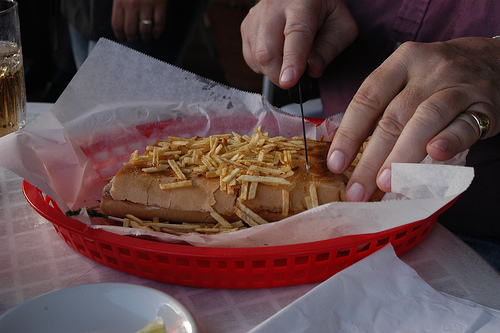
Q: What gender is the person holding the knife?
A: Male.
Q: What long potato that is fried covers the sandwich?
A: French fries.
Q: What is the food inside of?
A: A food basket.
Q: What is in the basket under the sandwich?
A: White paper.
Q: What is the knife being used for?
A: Cutting the sandwich.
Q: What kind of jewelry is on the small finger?
A: A ring.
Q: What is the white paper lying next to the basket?
A: A napkin.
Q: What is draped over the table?
A: A white tablecloth.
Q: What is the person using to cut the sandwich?
A: A knife.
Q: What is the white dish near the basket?
A: A small plate.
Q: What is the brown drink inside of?
A: A glass cup.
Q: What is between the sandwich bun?
A: Meat.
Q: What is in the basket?
A: Food.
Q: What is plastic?
A: A basket.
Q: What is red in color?
A: The basket.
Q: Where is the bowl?
A: On the table.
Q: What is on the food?
A: A hand with a knife.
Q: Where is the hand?
A: On the sandwich.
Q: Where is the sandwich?
A: In a basket.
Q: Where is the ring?
A: On the hand.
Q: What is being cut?
A: Sandwich.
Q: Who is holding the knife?
A: The man.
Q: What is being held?
A: Knife.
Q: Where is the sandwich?
A: In the basket.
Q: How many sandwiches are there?
A: One.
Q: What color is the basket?
A: Red.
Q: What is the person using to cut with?
A: A knife.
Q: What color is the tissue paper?
A: White.